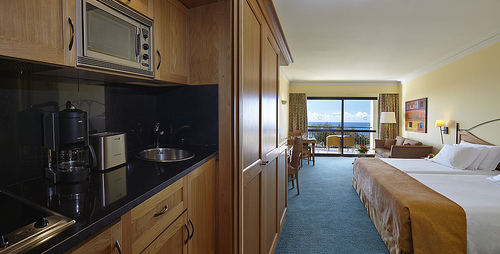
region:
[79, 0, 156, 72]
a modern microwave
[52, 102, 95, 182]
an electric coffre maker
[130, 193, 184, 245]
a wooden brown drawer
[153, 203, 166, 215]
teh metal handle of the drawer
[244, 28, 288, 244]
this lloks like a big closet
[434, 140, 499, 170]
some white pillows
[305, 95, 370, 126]
a blue sky in the very distance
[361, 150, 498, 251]
a couple of beds well fixed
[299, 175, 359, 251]
the floor is blue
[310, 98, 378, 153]
a large crystal window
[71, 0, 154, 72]
A silver microwave oven.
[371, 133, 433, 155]
A beige sofa.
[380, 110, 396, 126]
A white lamp shade.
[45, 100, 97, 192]
A coffee maker.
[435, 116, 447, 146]
A wall lamp.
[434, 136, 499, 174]
A pair of pillows.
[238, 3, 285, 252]
Wooden cabinet doors.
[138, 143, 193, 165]
A stainless steel sink.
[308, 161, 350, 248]
The blue rug.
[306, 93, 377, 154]
A large window.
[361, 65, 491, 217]
a bed in a room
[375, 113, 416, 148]
a lamp in a room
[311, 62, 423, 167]
a window on a truck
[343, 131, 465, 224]
a blanket on a bed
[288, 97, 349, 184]
a chair in a room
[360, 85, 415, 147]
curtains on a window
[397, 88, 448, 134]
a picture on a wall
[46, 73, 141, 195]
a coffee pot in a kitchen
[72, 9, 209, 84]
a microwave in a kitchen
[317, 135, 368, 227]
carpet on the floor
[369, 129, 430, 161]
Couch against the wall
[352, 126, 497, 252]
Bed against the wall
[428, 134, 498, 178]
White pillows on bed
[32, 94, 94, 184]
Coffeemaker on the counter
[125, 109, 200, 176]
Sink in the corner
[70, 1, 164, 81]
Mircrowave over the counter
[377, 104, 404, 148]
Lamp next to the couch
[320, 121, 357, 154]
Bench on the balcony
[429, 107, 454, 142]
Light on the wall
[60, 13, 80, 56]
Handle on the cabinet